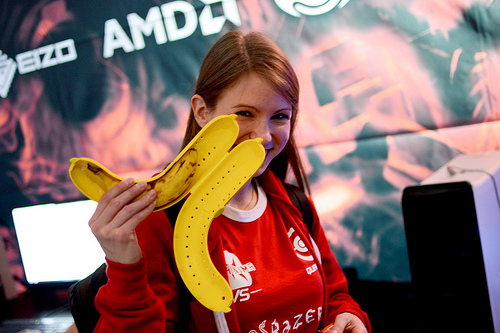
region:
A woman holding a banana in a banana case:
[58, 25, 380, 330]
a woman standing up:
[132, 66, 428, 325]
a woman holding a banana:
[42, 18, 449, 331]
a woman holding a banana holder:
[64, 32, 364, 329]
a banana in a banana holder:
[66, 90, 348, 323]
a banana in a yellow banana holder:
[99, 81, 341, 316]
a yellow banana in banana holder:
[111, 121, 294, 316]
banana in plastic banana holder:
[90, 94, 283, 326]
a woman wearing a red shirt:
[25, 13, 390, 330]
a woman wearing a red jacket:
[162, 133, 282, 298]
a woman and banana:
[62, 101, 319, 326]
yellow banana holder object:
[62, 128, 277, 308]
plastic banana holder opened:
[70, 115, 280, 327]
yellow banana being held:
[97, 133, 204, 211]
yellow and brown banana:
[75, 146, 209, 207]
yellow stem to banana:
[84, 165, 104, 192]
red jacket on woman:
[108, 172, 345, 332]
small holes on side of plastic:
[181, 166, 233, 226]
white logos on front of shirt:
[210, 249, 317, 331]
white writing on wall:
[95, 2, 200, 64]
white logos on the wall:
[0, 0, 240, 131]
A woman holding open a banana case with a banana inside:
[55, 25, 367, 330]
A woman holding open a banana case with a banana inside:
[63, 25, 378, 330]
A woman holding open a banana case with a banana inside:
[55, 25, 388, 331]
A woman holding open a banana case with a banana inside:
[58, 20, 373, 331]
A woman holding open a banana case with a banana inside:
[52, 27, 372, 327]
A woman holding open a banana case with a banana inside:
[53, 22, 377, 331]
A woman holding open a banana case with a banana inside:
[55, 25, 372, 331]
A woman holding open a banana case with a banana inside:
[62, 21, 374, 331]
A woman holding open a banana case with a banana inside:
[49, 24, 376, 331]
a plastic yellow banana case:
[64, 108, 271, 325]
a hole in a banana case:
[197, 195, 207, 204]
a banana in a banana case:
[82, 144, 202, 207]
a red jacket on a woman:
[94, 171, 373, 331]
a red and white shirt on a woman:
[212, 185, 325, 331]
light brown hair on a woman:
[177, 29, 315, 197]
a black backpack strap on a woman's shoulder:
[282, 180, 317, 230]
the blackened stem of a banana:
[85, 161, 101, 176]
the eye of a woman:
[269, 110, 291, 123]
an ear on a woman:
[188, 93, 209, 126]